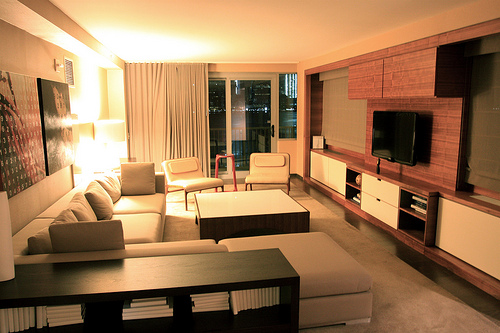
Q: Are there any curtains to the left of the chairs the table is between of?
A: Yes, there are curtains to the left of the chairs.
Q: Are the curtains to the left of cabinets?
A: No, the curtains are to the left of the chairs.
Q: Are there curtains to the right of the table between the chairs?
A: No, the curtains are to the left of the table.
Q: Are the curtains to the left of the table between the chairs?
A: Yes, the curtains are to the left of the table.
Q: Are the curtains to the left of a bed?
A: No, the curtains are to the left of the table.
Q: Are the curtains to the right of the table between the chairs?
A: No, the curtains are to the left of the table.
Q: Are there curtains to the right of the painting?
A: Yes, there are curtains to the right of the painting.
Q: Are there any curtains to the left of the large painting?
A: No, the curtains are to the right of the painting.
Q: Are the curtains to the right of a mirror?
A: No, the curtains are to the right of a painting.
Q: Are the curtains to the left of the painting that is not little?
A: No, the curtains are to the right of the painting.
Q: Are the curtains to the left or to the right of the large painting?
A: The curtains are to the right of the painting.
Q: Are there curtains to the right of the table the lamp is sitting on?
A: Yes, there are curtains to the right of the table.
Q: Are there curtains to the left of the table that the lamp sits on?
A: No, the curtains are to the right of the table.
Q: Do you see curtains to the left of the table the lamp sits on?
A: No, the curtains are to the right of the table.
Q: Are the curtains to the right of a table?
A: Yes, the curtains are to the right of a table.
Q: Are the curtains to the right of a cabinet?
A: No, the curtains are to the right of a table.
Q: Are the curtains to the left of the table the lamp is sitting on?
A: No, the curtains are to the right of the table.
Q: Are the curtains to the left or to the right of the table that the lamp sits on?
A: The curtains are to the right of the table.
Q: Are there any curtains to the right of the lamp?
A: Yes, there are curtains to the right of the lamp.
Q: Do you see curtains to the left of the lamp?
A: No, the curtains are to the right of the lamp.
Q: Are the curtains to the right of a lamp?
A: Yes, the curtains are to the right of a lamp.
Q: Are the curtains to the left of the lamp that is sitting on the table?
A: No, the curtains are to the right of the lamp.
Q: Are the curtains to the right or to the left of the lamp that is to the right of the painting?
A: The curtains are to the right of the lamp.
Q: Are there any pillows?
A: Yes, there is a pillow.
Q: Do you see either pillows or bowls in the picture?
A: Yes, there is a pillow.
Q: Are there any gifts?
A: No, there are no gifts.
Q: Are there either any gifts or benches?
A: No, there are no gifts or benches.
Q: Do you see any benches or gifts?
A: No, there are no gifts or benches.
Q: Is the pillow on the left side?
A: Yes, the pillow is on the left of the image.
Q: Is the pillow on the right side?
A: No, the pillow is on the left of the image.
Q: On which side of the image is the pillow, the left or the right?
A: The pillow is on the left of the image.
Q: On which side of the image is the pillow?
A: The pillow is on the left of the image.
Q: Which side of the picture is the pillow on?
A: The pillow is on the left of the image.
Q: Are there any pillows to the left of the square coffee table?
A: Yes, there is a pillow to the left of the coffee table.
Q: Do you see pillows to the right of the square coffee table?
A: No, the pillow is to the left of the coffee table.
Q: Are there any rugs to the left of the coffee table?
A: No, there is a pillow to the left of the coffee table.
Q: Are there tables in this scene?
A: Yes, there is a table.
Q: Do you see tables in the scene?
A: Yes, there is a table.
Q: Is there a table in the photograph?
A: Yes, there is a table.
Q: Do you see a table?
A: Yes, there is a table.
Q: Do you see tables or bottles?
A: Yes, there is a table.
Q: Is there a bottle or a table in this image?
A: Yes, there is a table.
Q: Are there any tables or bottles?
A: Yes, there is a table.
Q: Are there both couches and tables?
A: Yes, there are both a table and a couch.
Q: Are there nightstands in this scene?
A: No, there are no nightstands.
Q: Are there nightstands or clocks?
A: No, there are no nightstands or clocks.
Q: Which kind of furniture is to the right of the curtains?
A: The piece of furniture is a table.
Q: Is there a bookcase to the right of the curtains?
A: No, there is a table to the right of the curtains.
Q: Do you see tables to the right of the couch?
A: Yes, there is a table to the right of the couch.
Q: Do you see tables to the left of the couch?
A: No, the table is to the right of the couch.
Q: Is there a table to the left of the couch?
A: No, the table is to the right of the couch.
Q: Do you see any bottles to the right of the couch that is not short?
A: No, there is a table to the right of the couch.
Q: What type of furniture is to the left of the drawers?
A: The piece of furniture is a table.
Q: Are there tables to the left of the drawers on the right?
A: Yes, there is a table to the left of the drawers.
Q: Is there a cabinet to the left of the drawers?
A: No, there is a table to the left of the drawers.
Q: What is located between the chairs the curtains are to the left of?
A: The table is between the chairs.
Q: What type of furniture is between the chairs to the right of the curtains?
A: The piece of furniture is a table.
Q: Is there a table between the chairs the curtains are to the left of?
A: Yes, there is a table between the chairs.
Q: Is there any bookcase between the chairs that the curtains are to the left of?
A: No, there is a table between the chairs.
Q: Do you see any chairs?
A: Yes, there is a chair.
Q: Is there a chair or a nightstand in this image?
A: Yes, there is a chair.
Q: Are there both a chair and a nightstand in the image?
A: No, there is a chair but no nightstands.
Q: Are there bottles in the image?
A: No, there are no bottles.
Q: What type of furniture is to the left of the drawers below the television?
A: The piece of furniture is a chair.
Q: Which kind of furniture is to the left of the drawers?
A: The piece of furniture is a chair.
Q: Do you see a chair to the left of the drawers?
A: Yes, there is a chair to the left of the drawers.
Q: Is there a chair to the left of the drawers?
A: Yes, there is a chair to the left of the drawers.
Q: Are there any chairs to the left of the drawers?
A: Yes, there is a chair to the left of the drawers.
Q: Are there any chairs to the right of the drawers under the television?
A: No, the chair is to the left of the drawers.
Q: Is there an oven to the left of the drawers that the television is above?
A: No, there is a chair to the left of the drawers.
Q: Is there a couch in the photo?
A: Yes, there is a couch.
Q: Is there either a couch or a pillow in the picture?
A: Yes, there is a couch.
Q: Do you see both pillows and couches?
A: Yes, there are both a couch and pillows.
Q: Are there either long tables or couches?
A: Yes, there is a long couch.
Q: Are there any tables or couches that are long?
A: Yes, the couch is long.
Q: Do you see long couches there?
A: Yes, there is a long couch.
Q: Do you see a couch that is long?
A: Yes, there is a couch that is long.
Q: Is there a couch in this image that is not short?
A: Yes, there is a long couch.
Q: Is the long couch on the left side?
A: Yes, the couch is on the left of the image.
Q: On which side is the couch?
A: The couch is on the left of the image.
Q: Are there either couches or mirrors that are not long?
A: No, there is a couch but it is long.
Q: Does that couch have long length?
A: Yes, the couch is long.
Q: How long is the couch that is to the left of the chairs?
A: The couch is long.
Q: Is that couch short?
A: No, the couch is long.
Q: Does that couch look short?
A: No, the couch is long.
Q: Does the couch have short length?
A: No, the couch is long.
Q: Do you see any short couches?
A: No, there is a couch but it is long.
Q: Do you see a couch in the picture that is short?
A: No, there is a couch but it is long.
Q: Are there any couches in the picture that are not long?
A: No, there is a couch but it is long.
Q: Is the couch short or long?
A: The couch is long.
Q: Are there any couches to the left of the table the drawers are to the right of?
A: Yes, there is a couch to the left of the table.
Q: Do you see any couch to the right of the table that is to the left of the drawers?
A: No, the couch is to the left of the table.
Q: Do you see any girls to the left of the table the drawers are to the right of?
A: No, there is a couch to the left of the table.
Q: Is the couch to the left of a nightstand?
A: No, the couch is to the left of the table.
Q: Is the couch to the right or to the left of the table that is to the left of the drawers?
A: The couch is to the left of the table.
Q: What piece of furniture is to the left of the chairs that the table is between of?
A: The piece of furniture is a couch.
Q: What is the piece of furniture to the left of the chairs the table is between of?
A: The piece of furniture is a couch.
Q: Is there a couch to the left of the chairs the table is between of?
A: Yes, there is a couch to the left of the chairs.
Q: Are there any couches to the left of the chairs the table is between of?
A: Yes, there is a couch to the left of the chairs.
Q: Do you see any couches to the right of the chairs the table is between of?
A: No, the couch is to the left of the chairs.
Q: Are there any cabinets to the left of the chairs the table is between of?
A: No, there is a couch to the left of the chairs.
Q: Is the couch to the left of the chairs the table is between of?
A: Yes, the couch is to the left of the chairs.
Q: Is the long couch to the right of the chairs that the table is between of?
A: No, the couch is to the left of the chairs.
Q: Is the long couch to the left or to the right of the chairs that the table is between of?
A: The couch is to the left of the chairs.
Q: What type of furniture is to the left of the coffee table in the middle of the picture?
A: The piece of furniture is a couch.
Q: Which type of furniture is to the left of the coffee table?
A: The piece of furniture is a couch.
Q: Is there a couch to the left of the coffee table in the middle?
A: Yes, there is a couch to the left of the coffee table.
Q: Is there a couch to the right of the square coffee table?
A: No, the couch is to the left of the coffee table.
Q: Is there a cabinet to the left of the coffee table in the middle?
A: No, there is a couch to the left of the coffee table.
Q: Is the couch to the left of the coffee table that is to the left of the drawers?
A: Yes, the couch is to the left of the coffee table.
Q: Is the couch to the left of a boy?
A: No, the couch is to the left of the coffee table.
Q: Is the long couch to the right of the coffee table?
A: No, the couch is to the left of the coffee table.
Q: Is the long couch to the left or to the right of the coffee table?
A: The couch is to the left of the coffee table.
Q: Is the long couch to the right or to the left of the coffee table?
A: The couch is to the left of the coffee table.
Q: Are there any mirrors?
A: No, there are no mirrors.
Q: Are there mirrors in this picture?
A: No, there are no mirrors.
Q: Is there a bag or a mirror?
A: No, there are no mirrors or bags.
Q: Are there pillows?
A: Yes, there are pillows.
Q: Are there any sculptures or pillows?
A: Yes, there are pillows.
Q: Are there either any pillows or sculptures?
A: Yes, there are pillows.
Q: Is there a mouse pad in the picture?
A: No, there are no mouse pads.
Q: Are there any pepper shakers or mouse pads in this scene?
A: No, there are no mouse pads or pepper shakers.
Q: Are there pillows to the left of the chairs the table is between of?
A: Yes, there are pillows to the left of the chairs.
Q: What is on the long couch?
A: The pillows are on the couch.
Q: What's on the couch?
A: The pillows are on the couch.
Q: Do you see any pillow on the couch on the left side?
A: Yes, there are pillows on the couch.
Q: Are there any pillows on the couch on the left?
A: Yes, there are pillows on the couch.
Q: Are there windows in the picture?
A: Yes, there is a window.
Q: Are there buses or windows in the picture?
A: Yes, there is a window.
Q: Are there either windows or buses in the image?
A: Yes, there is a window.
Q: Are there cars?
A: No, there are no cars.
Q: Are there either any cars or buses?
A: No, there are no cars or buses.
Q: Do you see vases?
A: No, there are no vases.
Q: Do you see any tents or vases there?
A: No, there are no vases or tents.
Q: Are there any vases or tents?
A: No, there are no vases or tents.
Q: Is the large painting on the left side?
A: Yes, the painting is on the left of the image.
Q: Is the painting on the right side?
A: No, the painting is on the left of the image.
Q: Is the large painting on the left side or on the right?
A: The painting is on the left of the image.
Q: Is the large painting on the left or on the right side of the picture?
A: The painting is on the left of the image.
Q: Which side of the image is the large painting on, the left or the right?
A: The painting is on the left of the image.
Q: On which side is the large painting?
A: The painting is on the left of the image.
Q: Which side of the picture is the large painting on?
A: The painting is on the left of the image.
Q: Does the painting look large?
A: Yes, the painting is large.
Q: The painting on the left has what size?
A: The painting is large.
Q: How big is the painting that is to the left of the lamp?
A: The painting is large.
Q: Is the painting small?
A: No, the painting is large.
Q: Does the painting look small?
A: No, the painting is large.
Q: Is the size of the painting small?
A: No, the painting is large.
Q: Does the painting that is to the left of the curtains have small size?
A: No, the painting is large.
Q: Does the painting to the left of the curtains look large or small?
A: The painting is large.